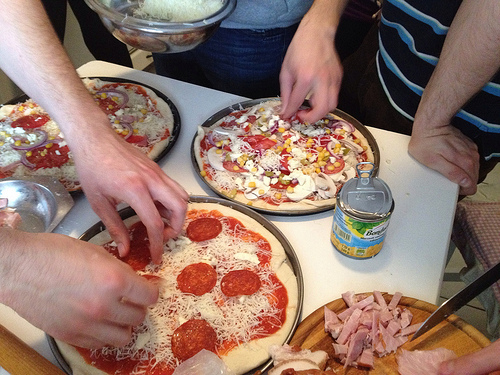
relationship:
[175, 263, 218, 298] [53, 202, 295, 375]
pepperoni on pizza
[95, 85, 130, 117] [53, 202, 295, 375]
onion on pizza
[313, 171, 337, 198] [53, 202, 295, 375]
mushroom on pizza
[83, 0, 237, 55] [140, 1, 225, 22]
bowl full of cheese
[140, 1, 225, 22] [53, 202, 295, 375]
cheese on pizza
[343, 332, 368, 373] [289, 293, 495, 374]
ham on plate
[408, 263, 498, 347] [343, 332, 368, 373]
knife by ham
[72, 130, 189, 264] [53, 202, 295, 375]
hand near pizza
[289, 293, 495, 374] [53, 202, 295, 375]
plate and pizza